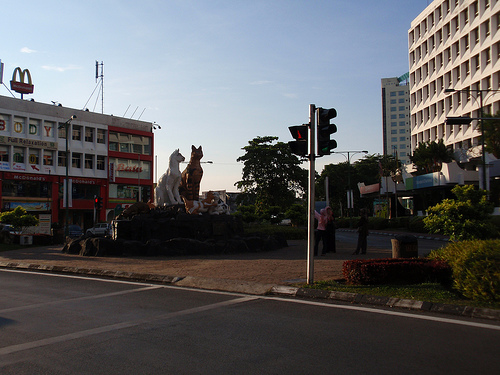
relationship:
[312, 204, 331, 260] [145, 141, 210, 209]
person admiring a statue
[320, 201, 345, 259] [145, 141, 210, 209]
person admiring a statue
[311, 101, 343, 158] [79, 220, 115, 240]
light for vehicles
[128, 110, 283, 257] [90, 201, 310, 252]
statues in center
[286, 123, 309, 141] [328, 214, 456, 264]
light hanging over street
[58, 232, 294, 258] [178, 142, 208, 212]
rocks surounding statue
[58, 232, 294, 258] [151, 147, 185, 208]
rocks surounding statue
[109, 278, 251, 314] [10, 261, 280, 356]
white lines for cross walk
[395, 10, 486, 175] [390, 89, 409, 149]
tall building with windows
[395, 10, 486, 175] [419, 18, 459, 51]
tall building with windows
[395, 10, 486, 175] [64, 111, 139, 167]
tall building with windows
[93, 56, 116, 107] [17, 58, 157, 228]
sign on top building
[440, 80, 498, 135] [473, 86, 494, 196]
street lights on post